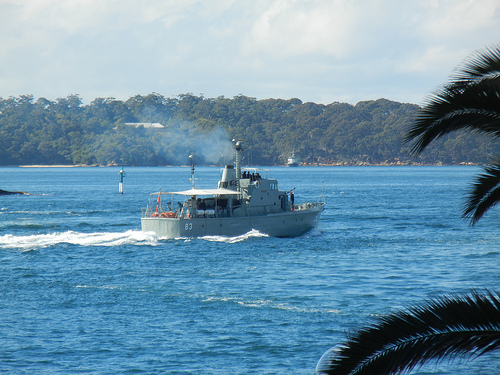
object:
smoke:
[209, 147, 221, 154]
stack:
[223, 162, 236, 175]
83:
[184, 223, 192, 231]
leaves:
[442, 130, 452, 137]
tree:
[314, 296, 496, 373]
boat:
[140, 141, 325, 236]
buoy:
[118, 167, 125, 196]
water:
[188, 290, 207, 300]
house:
[277, 148, 299, 167]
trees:
[310, 128, 325, 140]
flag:
[155, 193, 162, 212]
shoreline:
[327, 161, 361, 166]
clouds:
[48, 8, 66, 20]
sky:
[371, 35, 398, 54]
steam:
[166, 133, 187, 146]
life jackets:
[162, 213, 164, 217]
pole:
[191, 163, 196, 176]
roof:
[281, 149, 297, 156]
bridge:
[210, 206, 256, 217]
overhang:
[167, 188, 241, 196]